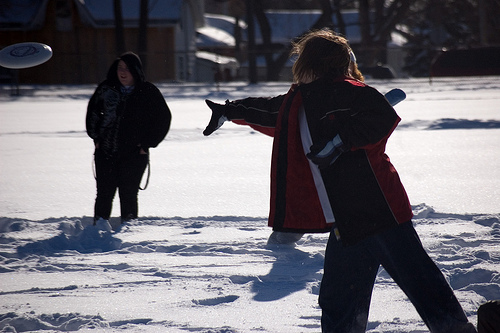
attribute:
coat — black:
[84, 67, 172, 149]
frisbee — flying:
[0, 39, 61, 76]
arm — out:
[201, 91, 296, 141]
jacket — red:
[258, 78, 421, 224]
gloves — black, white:
[305, 123, 349, 170]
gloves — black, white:
[202, 92, 226, 132]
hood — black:
[111, 46, 147, 67]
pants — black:
[314, 212, 476, 332]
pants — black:
[96, 155, 145, 213]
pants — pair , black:
[318, 227, 476, 332]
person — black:
[197, 29, 476, 331]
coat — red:
[296, 86, 423, 191]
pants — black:
[317, 204, 479, 331]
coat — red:
[225, 79, 412, 232]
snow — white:
[170, 240, 232, 296]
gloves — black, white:
[201, 91, 233, 139]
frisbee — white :
[4, 34, 61, 81]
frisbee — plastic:
[3, 39, 52, 76]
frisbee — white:
[11, 36, 89, 83]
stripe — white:
[295, 102, 335, 224]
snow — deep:
[14, 225, 292, 330]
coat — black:
[79, 79, 172, 151]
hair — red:
[285, 24, 364, 85]